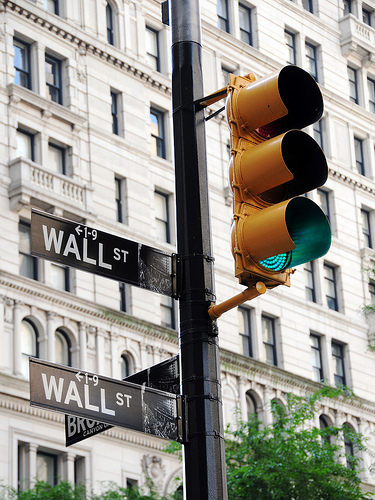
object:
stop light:
[234, 128, 331, 209]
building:
[1, 0, 374, 499]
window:
[309, 332, 321, 350]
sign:
[28, 206, 177, 297]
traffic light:
[224, 60, 331, 290]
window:
[12, 35, 30, 76]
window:
[43, 54, 63, 92]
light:
[241, 196, 330, 274]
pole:
[169, 0, 227, 499]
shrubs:
[0, 381, 375, 500]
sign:
[27, 356, 180, 442]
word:
[67, 414, 100, 437]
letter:
[97, 241, 114, 270]